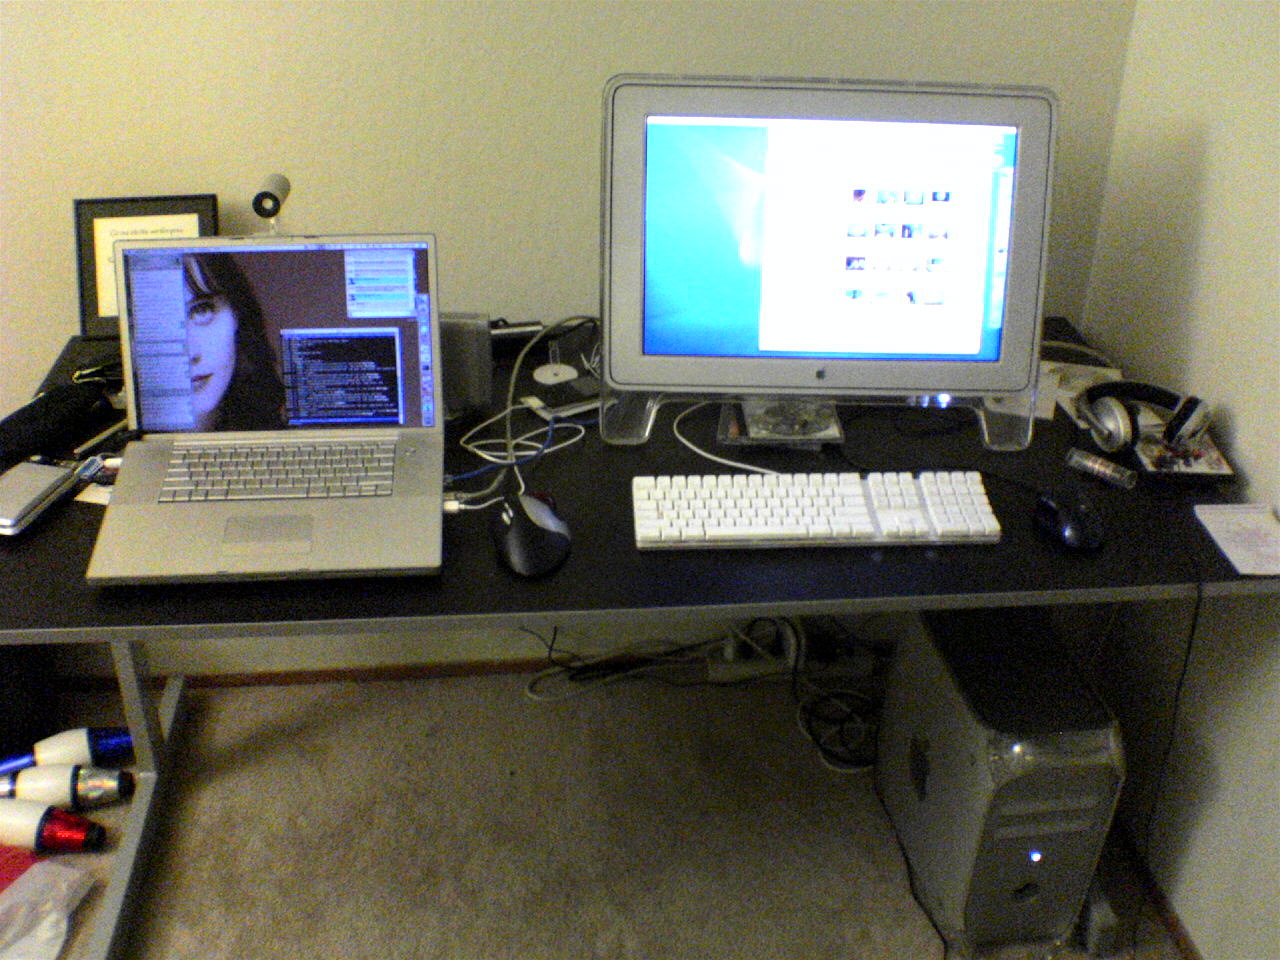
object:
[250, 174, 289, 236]
webcam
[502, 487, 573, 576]
mouse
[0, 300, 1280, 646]
table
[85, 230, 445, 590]
computer